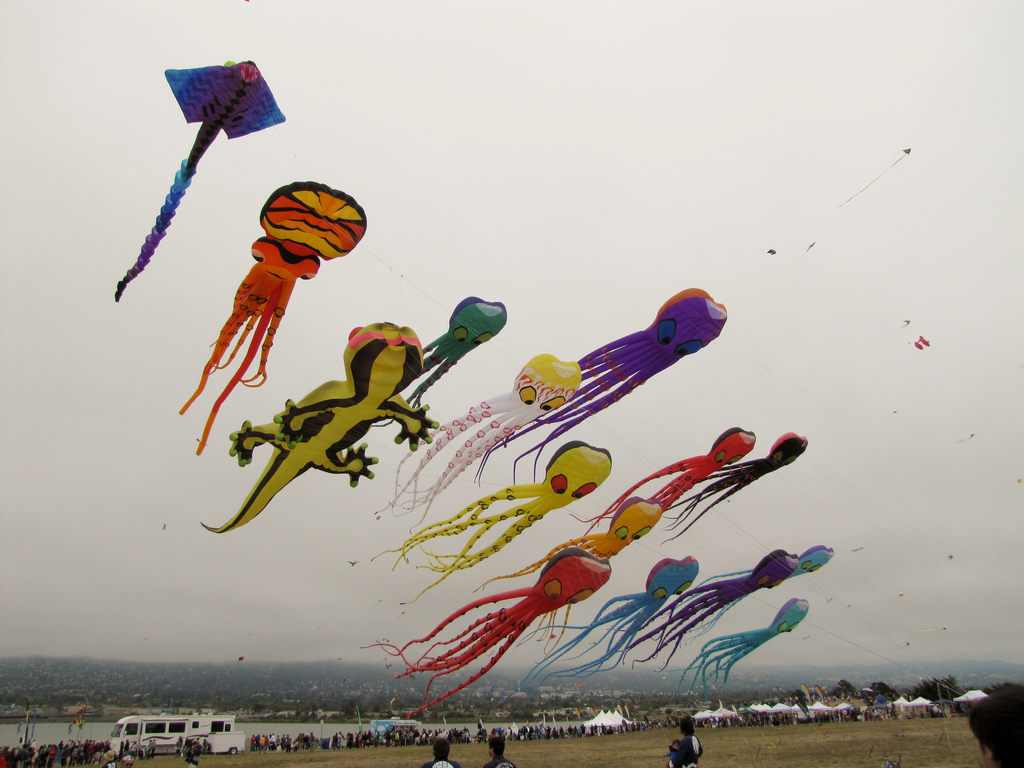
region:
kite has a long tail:
[105, 162, 210, 303]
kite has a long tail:
[183, 304, 247, 413]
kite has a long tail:
[196, 307, 274, 448]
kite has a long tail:
[203, 456, 302, 533]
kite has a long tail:
[384, 594, 549, 705]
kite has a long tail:
[554, 597, 656, 678]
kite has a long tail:
[566, 456, 696, 520]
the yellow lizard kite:
[199, 320, 438, 551]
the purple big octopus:
[484, 290, 732, 481]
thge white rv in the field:
[110, 711, 247, 765]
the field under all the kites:
[106, 701, 976, 766]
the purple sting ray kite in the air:
[108, 41, 286, 304]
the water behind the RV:
[8, 717, 601, 755]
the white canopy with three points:
[582, 709, 636, 728]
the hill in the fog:
[0, 654, 1018, 708]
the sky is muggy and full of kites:
[2, 1, 1023, 665]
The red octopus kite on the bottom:
[356, 546, 616, 725]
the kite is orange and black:
[176, 186, 366, 455]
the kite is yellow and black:
[202, 320, 430, 535]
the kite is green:
[404, 298, 503, 403]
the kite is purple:
[471, 288, 727, 486]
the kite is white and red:
[376, 354, 579, 525]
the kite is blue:
[522, 559, 693, 689]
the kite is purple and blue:
[116, 54, 288, 302]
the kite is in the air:
[126, 60, 820, 702]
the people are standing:
[9, 693, 993, 763]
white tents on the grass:
[581, 686, 987, 729]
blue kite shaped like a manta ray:
[107, 54, 288, 312]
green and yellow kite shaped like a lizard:
[193, 315, 443, 537]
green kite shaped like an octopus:
[410, 294, 512, 403]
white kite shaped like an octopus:
[386, 351, 583, 519]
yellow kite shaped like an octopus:
[376, 440, 614, 597]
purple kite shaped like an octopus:
[473, 285, 731, 489]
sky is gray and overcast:
[2, 6, 1023, 664]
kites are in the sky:
[2, 0, 1023, 703]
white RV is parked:
[107, 708, 244, 756]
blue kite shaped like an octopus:
[509, 553, 697, 686]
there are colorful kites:
[24, 23, 1018, 766]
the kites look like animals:
[87, 40, 974, 767]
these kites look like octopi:
[479, 285, 960, 750]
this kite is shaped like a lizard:
[155, 287, 503, 557]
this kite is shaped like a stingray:
[63, 13, 298, 365]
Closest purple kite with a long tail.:
[98, 48, 295, 306]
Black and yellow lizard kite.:
[201, 319, 430, 534]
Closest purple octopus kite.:
[525, 287, 750, 427]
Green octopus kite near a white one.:
[416, 298, 521, 404]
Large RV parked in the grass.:
[107, 708, 244, 754]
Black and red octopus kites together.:
[632, 414, 813, 526]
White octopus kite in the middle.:
[400, 354, 587, 492]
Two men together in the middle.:
[419, 729, 519, 767]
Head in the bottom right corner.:
[964, 674, 1018, 764]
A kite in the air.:
[514, 551, 712, 719]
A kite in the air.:
[653, 525, 800, 681]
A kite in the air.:
[691, 522, 844, 634]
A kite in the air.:
[407, 555, 629, 714]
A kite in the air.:
[520, 490, 685, 658]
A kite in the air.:
[613, 399, 744, 564]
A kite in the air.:
[699, 400, 804, 553]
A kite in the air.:
[389, 438, 617, 594]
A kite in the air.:
[356, 359, 612, 518]